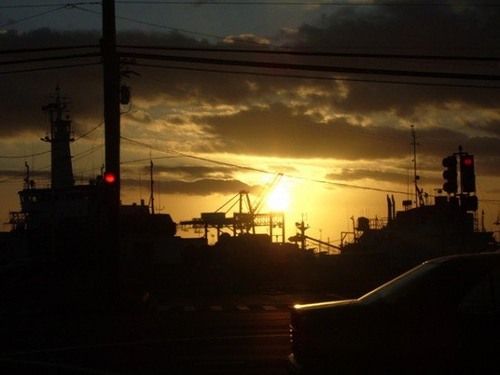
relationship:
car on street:
[280, 245, 497, 367] [25, 281, 286, 372]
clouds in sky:
[272, 93, 352, 139] [233, 70, 321, 143]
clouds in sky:
[297, 79, 387, 175] [315, 109, 362, 153]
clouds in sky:
[325, 65, 384, 118] [273, 114, 374, 175]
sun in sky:
[261, 188, 293, 213] [270, 107, 360, 160]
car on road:
[288, 253, 500, 375] [218, 311, 308, 370]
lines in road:
[196, 286, 302, 321] [216, 306, 280, 357]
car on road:
[288, 253, 500, 375] [220, 316, 275, 361]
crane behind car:
[157, 168, 294, 232] [180, 206, 288, 270]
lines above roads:
[157, 29, 368, 101] [206, 285, 308, 367]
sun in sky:
[250, 176, 299, 217] [186, 91, 306, 171]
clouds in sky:
[238, 72, 331, 158] [192, 118, 358, 201]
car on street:
[288, 253, 500, 375] [167, 306, 255, 360]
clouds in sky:
[177, 44, 309, 133] [204, 89, 334, 198]